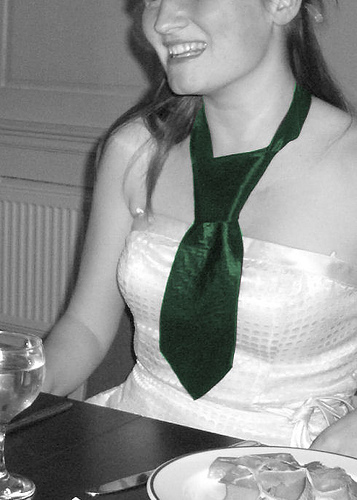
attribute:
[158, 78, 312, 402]
tie — green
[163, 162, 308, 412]
tie — green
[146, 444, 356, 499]
plate — white, round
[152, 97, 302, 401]
tie — green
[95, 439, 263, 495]
knife — small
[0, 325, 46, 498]
goblet — small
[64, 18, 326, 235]
hair — long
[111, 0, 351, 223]
hair — long